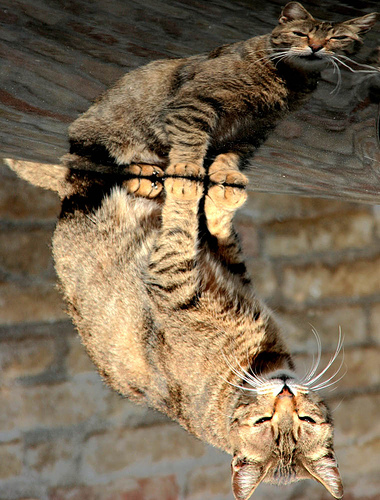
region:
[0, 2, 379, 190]
the reflection of a cat on the water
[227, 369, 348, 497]
the head of a cat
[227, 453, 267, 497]
the ear of a cat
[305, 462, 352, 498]
the ear of a cat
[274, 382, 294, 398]
the nose of a cat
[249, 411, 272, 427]
the eye of a cat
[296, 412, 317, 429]
the eye of a cat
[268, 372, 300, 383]
the mouth of a cat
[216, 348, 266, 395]
the whiskers of a cat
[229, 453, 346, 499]
the ears of a cat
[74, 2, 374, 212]
Cat with its mouth open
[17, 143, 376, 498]
Reflection of cat in the water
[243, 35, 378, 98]
White whiskers on cat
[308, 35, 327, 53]
Cat has brown and black nose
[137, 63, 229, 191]
Cat with black stripes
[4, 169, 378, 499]
Brick wall behind cat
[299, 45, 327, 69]
Cat has black lips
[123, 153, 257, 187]
Cat has brown paws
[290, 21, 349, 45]
Two black cat eyes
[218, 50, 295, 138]
Brown chest on cat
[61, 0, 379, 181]
the reflection of a cat in a puddle of water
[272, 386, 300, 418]
the nose of a cat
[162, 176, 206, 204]
the paw of a cat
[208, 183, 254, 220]
the paw of a cat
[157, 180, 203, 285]
the leg of a cat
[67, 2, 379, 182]
reflection of a cat in the water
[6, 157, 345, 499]
tabby cat is looking in the water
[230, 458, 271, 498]
cat has a pointy ear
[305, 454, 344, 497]
ear to the right of ear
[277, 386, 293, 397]
pink triangular nose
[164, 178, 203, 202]
paw touching paw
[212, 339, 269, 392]
cat has long white whiskers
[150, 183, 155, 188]
sharp white claw on paw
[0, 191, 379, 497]
brick wall behind the cat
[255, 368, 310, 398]
cat has a white muzzle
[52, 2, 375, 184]
a cat over a mirror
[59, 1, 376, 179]
a cat is color brown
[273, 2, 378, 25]
pointy ears of cat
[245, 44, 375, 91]
white whiskers of cat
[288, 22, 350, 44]
eyes of cat are semi closed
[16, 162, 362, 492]
reflection of cat on mirror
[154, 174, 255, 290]
front legs of cat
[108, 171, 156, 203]
back leg of cat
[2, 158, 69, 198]
the tail of cat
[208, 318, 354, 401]
whiskers of cat reflected on mirror